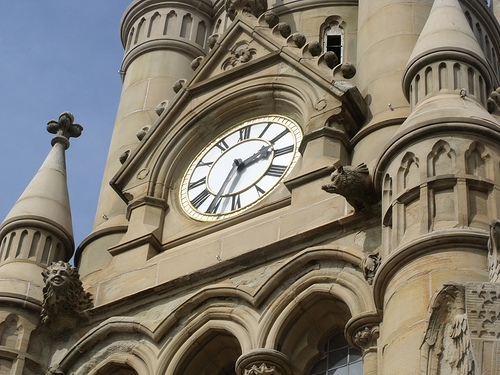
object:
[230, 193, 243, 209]
roman numerals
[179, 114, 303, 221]
clock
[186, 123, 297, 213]
2:35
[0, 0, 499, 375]
tower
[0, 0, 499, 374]
stone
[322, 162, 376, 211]
gargoyle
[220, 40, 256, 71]
crab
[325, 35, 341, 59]
window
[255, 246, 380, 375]
arch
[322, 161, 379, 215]
wolf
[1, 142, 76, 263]
cone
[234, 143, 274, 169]
short hand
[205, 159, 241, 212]
long hand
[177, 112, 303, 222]
gold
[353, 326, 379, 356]
flourish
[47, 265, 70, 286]
face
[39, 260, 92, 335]
statue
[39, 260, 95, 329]
hair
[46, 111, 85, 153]
top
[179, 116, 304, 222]
face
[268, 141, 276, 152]
point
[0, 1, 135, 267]
sky